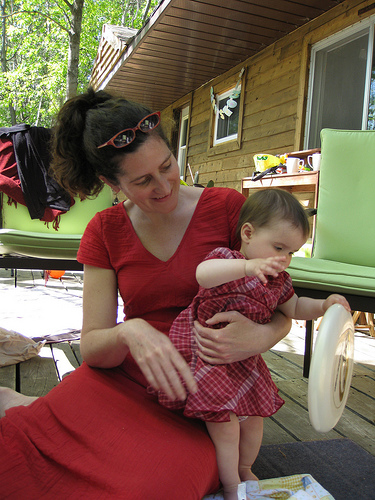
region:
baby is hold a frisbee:
[308, 294, 349, 433]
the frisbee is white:
[311, 299, 354, 434]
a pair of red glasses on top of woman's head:
[92, 110, 164, 149]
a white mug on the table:
[286, 154, 304, 174]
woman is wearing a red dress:
[0, 187, 237, 499]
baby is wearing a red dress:
[159, 247, 291, 426]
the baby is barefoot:
[214, 461, 255, 499]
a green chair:
[284, 119, 374, 379]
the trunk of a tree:
[62, 3, 83, 108]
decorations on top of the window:
[205, 67, 245, 117]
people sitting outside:
[40, 80, 345, 498]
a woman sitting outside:
[54, 71, 321, 428]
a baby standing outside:
[169, 167, 372, 471]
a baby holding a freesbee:
[188, 196, 366, 379]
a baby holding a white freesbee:
[169, 203, 373, 496]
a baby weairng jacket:
[174, 213, 374, 445]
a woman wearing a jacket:
[13, 111, 340, 498]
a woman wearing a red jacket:
[3, 151, 211, 474]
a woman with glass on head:
[81, 70, 279, 239]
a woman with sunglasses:
[76, 102, 268, 316]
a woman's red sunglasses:
[89, 109, 167, 148]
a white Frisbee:
[302, 302, 356, 432]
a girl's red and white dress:
[147, 246, 295, 422]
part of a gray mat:
[208, 435, 373, 498]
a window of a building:
[215, 93, 241, 139]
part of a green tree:
[0, 0, 154, 124]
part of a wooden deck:
[260, 316, 373, 462]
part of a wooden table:
[240, 172, 319, 199]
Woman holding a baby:
[2, 88, 353, 495]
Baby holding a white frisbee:
[165, 185, 356, 498]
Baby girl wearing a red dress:
[166, 188, 306, 425]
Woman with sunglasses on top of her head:
[53, 86, 185, 216]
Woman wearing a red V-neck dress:
[3, 87, 255, 497]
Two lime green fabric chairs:
[2, 121, 373, 318]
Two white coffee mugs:
[285, 150, 320, 174]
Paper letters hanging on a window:
[207, 76, 243, 122]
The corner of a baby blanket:
[232, 473, 352, 497]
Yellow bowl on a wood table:
[252, 150, 280, 175]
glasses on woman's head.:
[112, 111, 158, 153]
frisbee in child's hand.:
[314, 326, 343, 410]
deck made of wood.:
[31, 363, 46, 384]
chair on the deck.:
[341, 172, 359, 226]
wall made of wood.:
[261, 91, 288, 126]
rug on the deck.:
[19, 299, 61, 325]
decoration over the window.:
[207, 82, 239, 115]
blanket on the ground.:
[4, 339, 36, 363]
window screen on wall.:
[325, 54, 346, 111]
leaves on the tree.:
[84, 5, 104, 15]